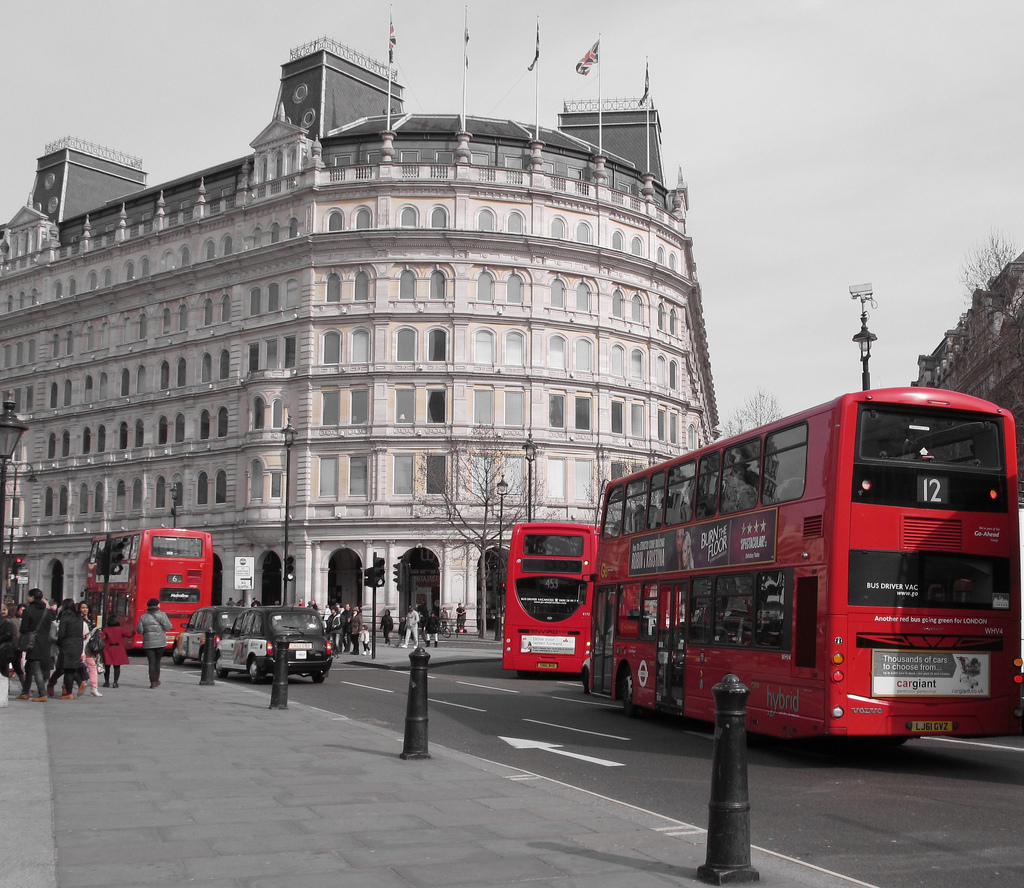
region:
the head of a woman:
[138, 590, 177, 629]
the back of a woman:
[138, 602, 181, 672]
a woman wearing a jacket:
[133, 593, 194, 669]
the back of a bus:
[777, 445, 997, 760]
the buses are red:
[87, 383, 1021, 748]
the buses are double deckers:
[84, 386, 1021, 750]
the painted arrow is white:
[494, 733, 624, 771]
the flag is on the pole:
[381, 13, 397, 132]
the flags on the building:
[1, 0, 720, 643]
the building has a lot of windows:
[0, 35, 722, 637]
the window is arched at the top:
[399, 269, 418, 299]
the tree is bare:
[433, 420, 547, 635]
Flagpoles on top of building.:
[335, 57, 674, 175]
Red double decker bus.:
[603, 432, 1022, 749]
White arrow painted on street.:
[492, 729, 620, 778]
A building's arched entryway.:
[397, 541, 449, 639]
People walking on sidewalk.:
[28, 591, 175, 693]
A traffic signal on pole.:
[367, 554, 386, 654]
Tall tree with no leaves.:
[452, 429, 503, 638]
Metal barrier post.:
[404, 647, 442, 756]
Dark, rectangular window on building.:
[430, 385, 453, 421]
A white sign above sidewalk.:
[228, 554, 390, 665]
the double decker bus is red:
[596, 383, 1021, 763]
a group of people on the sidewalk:
[11, 581, 185, 722]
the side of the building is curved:
[307, 113, 693, 625]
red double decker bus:
[584, 383, 1021, 757]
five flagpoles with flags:
[379, 9, 655, 180]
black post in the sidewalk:
[395, 647, 438, 761]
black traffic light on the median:
[360, 550, 392, 661]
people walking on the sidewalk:
[6, 582, 174, 706]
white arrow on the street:
[493, 729, 627, 774]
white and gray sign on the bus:
[868, 648, 993, 702]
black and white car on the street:
[223, 603, 334, 684]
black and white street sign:
[231, 553, 260, 593]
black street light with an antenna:
[849, 277, 879, 389]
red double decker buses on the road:
[60, 383, 1019, 748]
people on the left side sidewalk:
[13, 575, 207, 706]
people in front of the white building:
[319, 594, 472, 664]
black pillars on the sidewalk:
[190, 625, 773, 886]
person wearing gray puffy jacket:
[139, 588, 177, 693]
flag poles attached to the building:
[372, 10, 661, 173]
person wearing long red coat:
[98, 609, 134, 689]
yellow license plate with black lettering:
[897, 717, 951, 737]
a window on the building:
[406, 320, 449, 381]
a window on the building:
[430, 408, 473, 440]